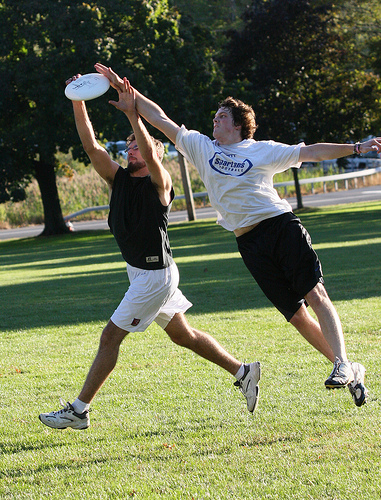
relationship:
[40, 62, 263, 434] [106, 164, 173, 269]
man wearing t-shirt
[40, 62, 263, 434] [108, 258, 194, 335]
man wearing shorts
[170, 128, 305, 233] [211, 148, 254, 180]
shirt with logo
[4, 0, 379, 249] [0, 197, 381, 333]
trees cast shadows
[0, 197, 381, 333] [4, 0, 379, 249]
shadows cast by trees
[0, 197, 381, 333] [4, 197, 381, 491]
shadows on grass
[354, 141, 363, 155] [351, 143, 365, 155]
bracelets on wrist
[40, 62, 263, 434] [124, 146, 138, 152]
man wearing glasses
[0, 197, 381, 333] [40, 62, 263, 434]
shadows cast by man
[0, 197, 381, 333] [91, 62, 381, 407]
shadows cast by man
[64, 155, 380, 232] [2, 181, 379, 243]
guard rail lining street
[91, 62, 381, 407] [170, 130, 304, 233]
man wearing shirt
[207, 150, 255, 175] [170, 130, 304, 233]
letters on shirt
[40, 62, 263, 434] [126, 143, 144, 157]
man wearing glasses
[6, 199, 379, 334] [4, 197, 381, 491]
shade on lawn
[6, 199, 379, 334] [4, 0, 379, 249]
shade by trees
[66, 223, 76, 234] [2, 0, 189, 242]
hydrant behind tree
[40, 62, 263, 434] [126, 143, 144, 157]
man has glasses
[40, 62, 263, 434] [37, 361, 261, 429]
man has tennis shoes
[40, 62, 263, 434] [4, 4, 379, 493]
man in air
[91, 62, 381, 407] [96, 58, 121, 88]
man has hand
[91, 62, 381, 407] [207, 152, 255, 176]
man has graphics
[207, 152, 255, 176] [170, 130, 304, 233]
graphics on shirt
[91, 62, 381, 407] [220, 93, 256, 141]
man has hair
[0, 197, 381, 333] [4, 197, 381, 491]
shadow on grass